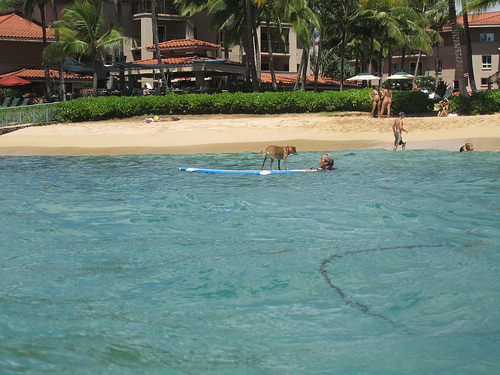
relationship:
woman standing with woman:
[369, 85, 382, 112] [379, 84, 394, 114]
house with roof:
[415, 9, 498, 88] [429, 9, 496, 29]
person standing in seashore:
[393, 110, 409, 149] [340, 147, 498, 161]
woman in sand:
[435, 94, 455, 121] [420, 117, 484, 145]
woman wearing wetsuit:
[435, 94, 455, 121] [440, 104, 447, 113]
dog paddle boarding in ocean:
[258, 142, 295, 167] [40, 173, 473, 321]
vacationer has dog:
[305, 153, 336, 172] [260, 145, 297, 169]